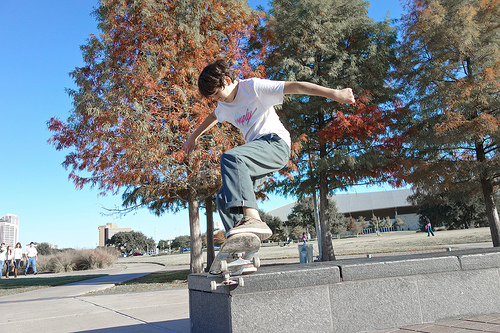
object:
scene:
[0, 0, 499, 333]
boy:
[181, 59, 356, 240]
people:
[0, 241, 38, 278]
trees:
[262, 0, 421, 261]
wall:
[185, 246, 499, 333]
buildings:
[0, 213, 19, 248]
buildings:
[98, 221, 114, 247]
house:
[268, 187, 426, 242]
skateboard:
[207, 232, 261, 290]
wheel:
[254, 255, 261, 267]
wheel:
[218, 258, 228, 270]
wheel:
[209, 279, 217, 291]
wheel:
[236, 276, 244, 287]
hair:
[196, 59, 235, 97]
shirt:
[211, 78, 291, 150]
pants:
[215, 134, 293, 229]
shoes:
[225, 215, 273, 241]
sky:
[1, 0, 499, 97]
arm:
[257, 78, 338, 104]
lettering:
[233, 107, 256, 126]